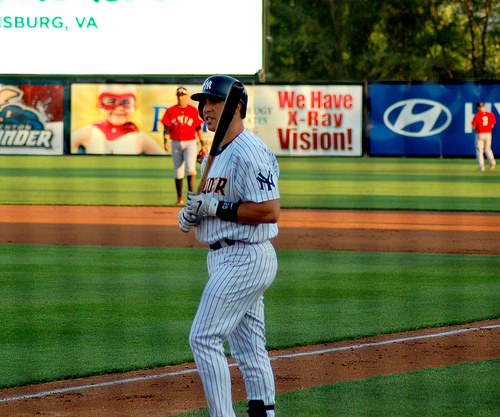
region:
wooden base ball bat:
[175, 66, 270, 253]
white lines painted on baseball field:
[306, 293, 498, 390]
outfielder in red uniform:
[462, 87, 499, 183]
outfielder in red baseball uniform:
[150, 81, 222, 244]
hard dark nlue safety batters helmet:
[186, 59, 254, 134]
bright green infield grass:
[15, 248, 138, 369]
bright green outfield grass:
[309, 158, 453, 207]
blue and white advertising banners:
[369, 73, 498, 155]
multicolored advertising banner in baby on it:
[70, 79, 377, 166]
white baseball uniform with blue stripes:
[182, 123, 337, 400]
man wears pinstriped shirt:
[191, 112, 288, 247]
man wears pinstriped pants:
[196, 242, 312, 410]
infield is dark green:
[4, 231, 491, 371]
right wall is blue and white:
[370, 85, 494, 152]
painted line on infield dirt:
[14, 292, 492, 407]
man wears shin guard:
[245, 387, 272, 415]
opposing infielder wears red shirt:
[158, 86, 203, 141]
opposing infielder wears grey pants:
[166, 142, 201, 180]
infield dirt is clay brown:
[9, 204, 499, 270]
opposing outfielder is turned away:
[470, 104, 498, 168]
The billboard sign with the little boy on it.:
[70, 77, 231, 152]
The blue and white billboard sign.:
[366, 77, 496, 148]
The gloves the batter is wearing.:
[170, 190, 230, 222]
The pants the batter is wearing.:
[185, 245, 275, 405]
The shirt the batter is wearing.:
[187, 150, 277, 235]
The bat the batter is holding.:
[190, 81, 240, 186]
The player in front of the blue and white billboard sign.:
[466, 100, 491, 170]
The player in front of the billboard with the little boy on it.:
[155, 81, 205, 201]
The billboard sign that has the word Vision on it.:
[242, 85, 359, 152]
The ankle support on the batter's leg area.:
[241, 387, 288, 414]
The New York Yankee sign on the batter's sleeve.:
[250, 167, 276, 189]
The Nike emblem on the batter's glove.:
[190, 191, 200, 211]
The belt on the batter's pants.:
[205, 230, 230, 245]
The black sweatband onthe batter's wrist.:
[215, 195, 240, 220]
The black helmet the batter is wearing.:
[190, 71, 255, 121]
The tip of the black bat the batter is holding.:
[200, 75, 240, 152]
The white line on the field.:
[3, 308, 498, 411]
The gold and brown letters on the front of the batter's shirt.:
[190, 165, 230, 195]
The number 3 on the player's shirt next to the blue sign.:
[476, 111, 486, 126]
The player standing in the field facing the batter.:
[152, 90, 197, 190]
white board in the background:
[0, 0, 270, 79]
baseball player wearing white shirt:
[177, 73, 289, 415]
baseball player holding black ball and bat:
[176, 72, 281, 412]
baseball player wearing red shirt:
[160, 80, 200, 205]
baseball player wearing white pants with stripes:
[181, 73, 283, 415]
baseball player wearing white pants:
[471, 102, 496, 174]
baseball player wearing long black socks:
[162, 86, 201, 212]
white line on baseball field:
[0, 314, 499, 412]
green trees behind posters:
[265, 2, 499, 77]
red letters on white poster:
[274, 84, 359, 154]